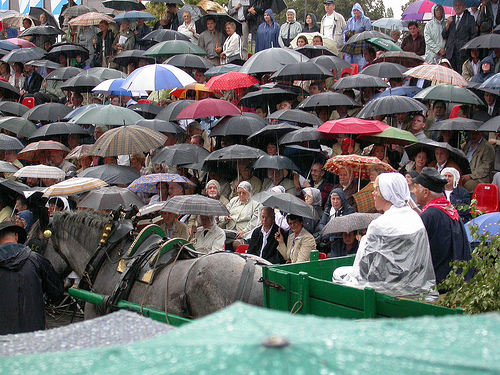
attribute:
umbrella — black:
[147, 190, 229, 225]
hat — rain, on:
[235, 179, 250, 191]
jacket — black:
[0, 246, 54, 320]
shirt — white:
[260, 230, 271, 254]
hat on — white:
[379, 171, 409, 203]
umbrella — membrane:
[175, 98, 235, 116]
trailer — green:
[259, 246, 449, 316]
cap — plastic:
[378, 170, 410, 204]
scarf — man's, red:
[421, 198, 463, 224]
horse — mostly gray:
[22, 185, 262, 314]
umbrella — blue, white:
[120, 56, 192, 95]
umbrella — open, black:
[257, 186, 323, 223]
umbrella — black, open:
[253, 153, 302, 172]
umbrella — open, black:
[200, 141, 266, 159]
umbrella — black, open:
[150, 137, 206, 166]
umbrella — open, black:
[72, 160, 139, 184]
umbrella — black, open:
[74, 183, 147, 210]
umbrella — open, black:
[0, 172, 35, 201]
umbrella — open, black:
[209, 109, 285, 149]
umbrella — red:
[311, 107, 395, 144]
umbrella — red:
[198, 70, 268, 100]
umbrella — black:
[148, 134, 211, 168]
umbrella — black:
[199, 144, 271, 184]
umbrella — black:
[210, 109, 273, 149]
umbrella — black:
[295, 89, 364, 119]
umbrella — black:
[237, 89, 306, 119]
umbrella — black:
[324, 71, 389, 105]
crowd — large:
[4, 4, 498, 322]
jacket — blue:
[255, 7, 284, 50]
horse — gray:
[32, 198, 266, 327]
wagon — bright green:
[57, 218, 498, 323]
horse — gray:
[28, 198, 284, 334]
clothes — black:
[4, 244, 62, 336]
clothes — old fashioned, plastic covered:
[339, 214, 433, 299]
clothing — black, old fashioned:
[422, 202, 476, 298]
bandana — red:
[415, 194, 462, 226]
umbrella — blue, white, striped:
[124, 64, 193, 93]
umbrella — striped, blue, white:
[90, 73, 146, 98]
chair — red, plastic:
[468, 180, 498, 209]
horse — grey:
[30, 207, 273, 327]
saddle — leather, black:
[102, 200, 198, 278]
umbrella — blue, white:
[113, 56, 189, 96]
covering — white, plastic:
[344, 211, 442, 307]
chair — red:
[466, 176, 498, 217]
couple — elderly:
[246, 209, 318, 278]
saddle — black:
[97, 202, 191, 283]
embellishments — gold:
[84, 216, 194, 292]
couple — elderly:
[342, 160, 480, 305]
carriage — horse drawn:
[264, 244, 493, 324]